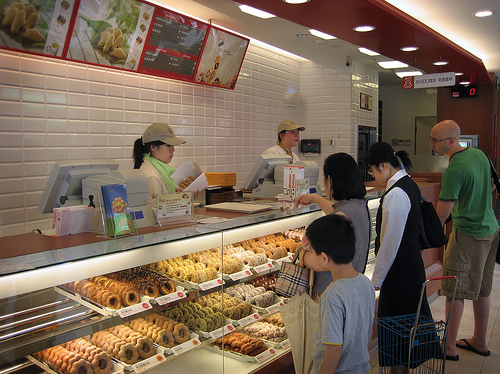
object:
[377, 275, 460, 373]
cart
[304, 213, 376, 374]
boy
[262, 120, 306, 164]
girl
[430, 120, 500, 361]
customer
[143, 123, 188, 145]
cap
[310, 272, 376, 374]
shirt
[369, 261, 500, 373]
ground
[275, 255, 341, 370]
closed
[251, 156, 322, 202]
register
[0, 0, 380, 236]
tiles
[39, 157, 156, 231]
cash register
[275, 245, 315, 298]
white/pink/blue purse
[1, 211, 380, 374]
doughnut display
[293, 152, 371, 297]
people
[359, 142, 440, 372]
people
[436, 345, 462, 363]
flip flop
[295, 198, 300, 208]
finger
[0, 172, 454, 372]
counter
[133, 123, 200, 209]
girl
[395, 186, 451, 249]
purse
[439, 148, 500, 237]
green shirt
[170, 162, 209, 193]
box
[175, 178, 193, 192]
doughnuts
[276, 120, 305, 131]
hat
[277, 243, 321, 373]
umbrella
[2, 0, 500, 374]
donut shop